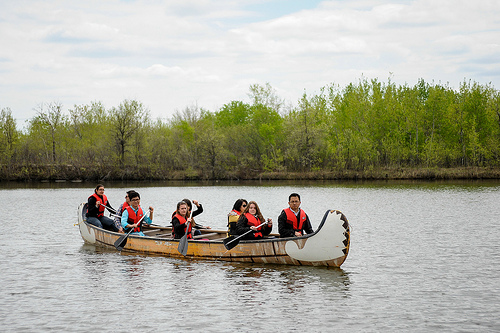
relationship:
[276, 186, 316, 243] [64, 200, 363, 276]
man in boat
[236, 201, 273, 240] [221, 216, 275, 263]
people holds oar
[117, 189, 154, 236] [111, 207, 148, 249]
man holds oar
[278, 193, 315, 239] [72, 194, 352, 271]
man in boat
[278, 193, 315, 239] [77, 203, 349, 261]
man in boat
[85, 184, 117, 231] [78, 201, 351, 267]
man in boat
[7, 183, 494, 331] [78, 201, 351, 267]
water under boat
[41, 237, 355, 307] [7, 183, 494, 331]
shadow in water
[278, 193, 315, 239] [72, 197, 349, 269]
man in kayak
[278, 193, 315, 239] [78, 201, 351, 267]
man in boat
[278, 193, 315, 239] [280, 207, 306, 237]
man wearing life jacket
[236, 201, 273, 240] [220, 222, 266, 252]
people has oar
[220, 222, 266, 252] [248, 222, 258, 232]
oar in hand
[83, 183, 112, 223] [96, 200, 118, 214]
man has oar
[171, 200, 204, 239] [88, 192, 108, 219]
people in life vest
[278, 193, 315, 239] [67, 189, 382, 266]
man in boat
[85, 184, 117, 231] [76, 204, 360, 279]
man in boat